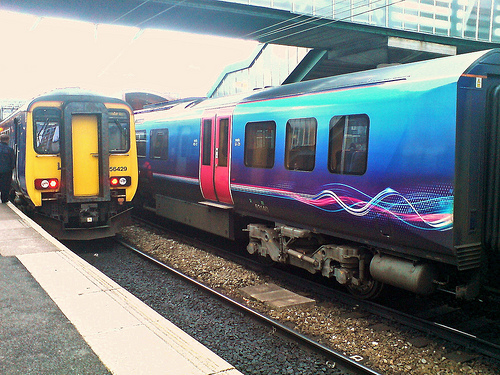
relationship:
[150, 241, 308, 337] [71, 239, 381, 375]
gravel between between tracks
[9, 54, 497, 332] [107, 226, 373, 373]
two trains on tracks on tracks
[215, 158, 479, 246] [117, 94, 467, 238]
wave on train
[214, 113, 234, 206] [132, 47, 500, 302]
door on purple and blue trai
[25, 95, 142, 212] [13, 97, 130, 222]
yellow rear on train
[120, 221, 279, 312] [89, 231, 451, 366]
brown dirt between tracks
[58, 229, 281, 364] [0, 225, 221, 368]
brown bricks on platform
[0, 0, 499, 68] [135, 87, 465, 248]
bridge above train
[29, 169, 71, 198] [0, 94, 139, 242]
headlights on train on black train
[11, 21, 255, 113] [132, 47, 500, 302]
bright grey sky above purple and blue trai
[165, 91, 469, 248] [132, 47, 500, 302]
blue wall on train on purple and blue trai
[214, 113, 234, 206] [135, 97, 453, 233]
door on train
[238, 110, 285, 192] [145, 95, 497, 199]
glass windows on train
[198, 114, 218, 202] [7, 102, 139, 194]
door on train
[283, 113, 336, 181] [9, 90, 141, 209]
glass window on train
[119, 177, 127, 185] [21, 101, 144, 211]
lights on back on train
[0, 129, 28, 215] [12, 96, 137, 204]
passenger boarding boarding train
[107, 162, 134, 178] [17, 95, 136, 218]
number decal on train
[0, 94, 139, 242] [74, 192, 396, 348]
black train on tracks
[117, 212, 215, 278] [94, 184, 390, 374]
gravel between between tracks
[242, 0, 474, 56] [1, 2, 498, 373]
staircase at station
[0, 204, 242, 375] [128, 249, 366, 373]
cement sidewalk near tracks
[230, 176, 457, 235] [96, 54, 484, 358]
colorful paint on train